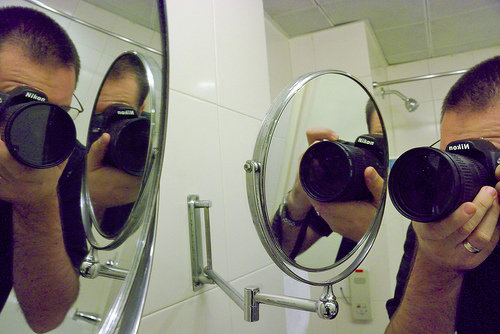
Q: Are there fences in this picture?
A: No, there are no fences.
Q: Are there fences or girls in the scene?
A: No, there are no fences or girls.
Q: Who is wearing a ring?
A: The man is wearing a ring.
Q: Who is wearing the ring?
A: The man is wearing a ring.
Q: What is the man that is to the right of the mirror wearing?
A: The man is wearing a ring.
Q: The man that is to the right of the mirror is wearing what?
A: The man is wearing a ring.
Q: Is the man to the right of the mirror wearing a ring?
A: Yes, the man is wearing a ring.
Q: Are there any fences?
A: No, there are no fences.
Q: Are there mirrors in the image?
A: Yes, there is a mirror.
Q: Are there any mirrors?
A: Yes, there is a mirror.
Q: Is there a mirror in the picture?
A: Yes, there is a mirror.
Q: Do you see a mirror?
A: Yes, there is a mirror.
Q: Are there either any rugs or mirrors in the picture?
A: Yes, there is a mirror.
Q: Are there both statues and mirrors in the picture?
A: No, there is a mirror but no statues.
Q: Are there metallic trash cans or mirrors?
A: Yes, there is a metal mirror.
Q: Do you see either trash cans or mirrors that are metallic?
A: Yes, the mirror is metallic.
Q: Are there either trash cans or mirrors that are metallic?
A: Yes, the mirror is metallic.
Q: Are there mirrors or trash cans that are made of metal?
A: Yes, the mirror is made of metal.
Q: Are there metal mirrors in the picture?
A: Yes, there is a metal mirror.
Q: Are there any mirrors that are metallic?
A: Yes, there is a mirror that is metallic.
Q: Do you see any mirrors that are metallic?
A: Yes, there is a mirror that is metallic.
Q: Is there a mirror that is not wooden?
A: Yes, there is a metallic mirror.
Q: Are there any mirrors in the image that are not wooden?
A: Yes, there is a metallic mirror.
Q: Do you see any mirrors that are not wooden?
A: Yes, there is a metallic mirror.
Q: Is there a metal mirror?
A: Yes, there is a mirror that is made of metal.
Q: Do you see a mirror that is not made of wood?
A: Yes, there is a mirror that is made of metal.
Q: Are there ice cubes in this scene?
A: No, there are no ice cubes.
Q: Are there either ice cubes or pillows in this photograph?
A: No, there are no ice cubes or pillows.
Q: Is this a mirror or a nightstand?
A: This is a mirror.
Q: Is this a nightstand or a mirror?
A: This is a mirror.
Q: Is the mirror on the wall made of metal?
A: Yes, the mirror is made of metal.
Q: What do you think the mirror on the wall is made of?
A: The mirror is made of metal.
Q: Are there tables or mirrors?
A: Yes, there is a mirror.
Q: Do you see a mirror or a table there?
A: Yes, there is a mirror.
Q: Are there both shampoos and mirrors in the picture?
A: No, there is a mirror but no shampoos.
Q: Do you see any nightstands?
A: No, there are no nightstands.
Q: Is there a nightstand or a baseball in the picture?
A: No, there are no nightstands or baseballs.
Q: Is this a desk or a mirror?
A: This is a mirror.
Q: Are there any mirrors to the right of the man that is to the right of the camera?
A: Yes, there is a mirror to the right of the man.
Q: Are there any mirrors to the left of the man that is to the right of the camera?
A: No, the mirror is to the right of the man.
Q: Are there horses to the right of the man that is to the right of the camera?
A: No, there is a mirror to the right of the man.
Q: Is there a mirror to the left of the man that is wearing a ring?
A: Yes, there is a mirror to the left of the man.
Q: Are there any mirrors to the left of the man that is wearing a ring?
A: Yes, there is a mirror to the left of the man.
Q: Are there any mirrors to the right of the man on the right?
A: No, the mirror is to the left of the man.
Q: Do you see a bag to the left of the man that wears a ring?
A: No, there is a mirror to the left of the man.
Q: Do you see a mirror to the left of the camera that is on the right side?
A: Yes, there is a mirror to the left of the camera.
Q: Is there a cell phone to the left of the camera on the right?
A: No, there is a mirror to the left of the camera.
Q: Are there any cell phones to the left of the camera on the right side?
A: No, there is a mirror to the left of the camera.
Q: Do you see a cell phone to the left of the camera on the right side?
A: No, there is a mirror to the left of the camera.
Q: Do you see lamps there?
A: No, there are no lamps.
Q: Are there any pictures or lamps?
A: No, there are no lamps or pictures.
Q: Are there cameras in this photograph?
A: Yes, there is a camera.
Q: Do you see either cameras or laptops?
A: Yes, there is a camera.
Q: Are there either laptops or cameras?
A: Yes, there is a camera.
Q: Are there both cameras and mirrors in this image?
A: Yes, there are both a camera and a mirror.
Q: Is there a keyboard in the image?
A: No, there are no keyboards.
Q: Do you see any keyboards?
A: No, there are no keyboards.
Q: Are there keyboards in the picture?
A: No, there are no keyboards.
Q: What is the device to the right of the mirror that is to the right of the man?
A: The device is a camera.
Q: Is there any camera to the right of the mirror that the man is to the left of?
A: Yes, there is a camera to the right of the mirror.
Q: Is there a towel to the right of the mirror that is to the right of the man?
A: No, there is a camera to the right of the mirror.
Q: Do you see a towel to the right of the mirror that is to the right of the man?
A: No, there is a camera to the right of the mirror.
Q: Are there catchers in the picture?
A: No, there are no catchers.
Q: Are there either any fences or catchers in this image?
A: No, there are no catchers or fences.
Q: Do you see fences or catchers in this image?
A: No, there are no catchers or fences.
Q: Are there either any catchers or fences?
A: No, there are no catchers or fences.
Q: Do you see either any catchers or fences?
A: No, there are no catchers or fences.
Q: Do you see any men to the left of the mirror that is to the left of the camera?
A: Yes, there is a man to the left of the mirror.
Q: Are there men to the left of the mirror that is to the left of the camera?
A: Yes, there is a man to the left of the mirror.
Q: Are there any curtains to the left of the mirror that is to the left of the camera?
A: No, there is a man to the left of the mirror.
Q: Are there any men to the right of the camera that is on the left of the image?
A: Yes, there is a man to the right of the camera.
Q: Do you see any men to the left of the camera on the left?
A: No, the man is to the right of the camera.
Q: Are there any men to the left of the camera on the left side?
A: No, the man is to the right of the camera.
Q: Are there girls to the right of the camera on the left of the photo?
A: No, there is a man to the right of the camera.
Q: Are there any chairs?
A: No, there are no chairs.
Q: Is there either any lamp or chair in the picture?
A: No, there are no chairs or lamps.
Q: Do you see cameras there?
A: Yes, there is a camera.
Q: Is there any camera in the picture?
A: Yes, there is a camera.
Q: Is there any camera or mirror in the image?
A: Yes, there is a camera.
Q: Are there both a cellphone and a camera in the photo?
A: No, there is a camera but no cell phones.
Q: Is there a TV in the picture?
A: No, there are no televisions.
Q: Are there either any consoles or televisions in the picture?
A: No, there are no televisions or consoles.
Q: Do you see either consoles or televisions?
A: No, there are no televisions or consoles.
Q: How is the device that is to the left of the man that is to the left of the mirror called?
A: The device is a camera.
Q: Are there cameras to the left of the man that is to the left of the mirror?
A: Yes, there is a camera to the left of the man.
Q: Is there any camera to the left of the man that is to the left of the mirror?
A: Yes, there is a camera to the left of the man.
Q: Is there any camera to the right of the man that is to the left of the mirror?
A: No, the camera is to the left of the man.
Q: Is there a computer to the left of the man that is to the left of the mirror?
A: No, there is a camera to the left of the man.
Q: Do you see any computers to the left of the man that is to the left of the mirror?
A: No, there is a camera to the left of the man.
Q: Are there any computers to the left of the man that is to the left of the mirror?
A: No, there is a camera to the left of the man.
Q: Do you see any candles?
A: No, there are no candles.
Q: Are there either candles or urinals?
A: No, there are no candles or urinals.